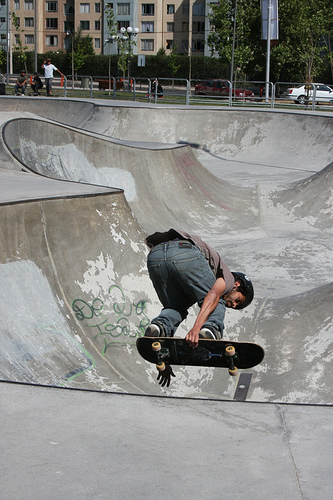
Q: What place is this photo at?
A: It is at the skate park.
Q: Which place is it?
A: It is a skate park.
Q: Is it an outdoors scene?
A: Yes, it is outdoors.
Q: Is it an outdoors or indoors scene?
A: It is outdoors.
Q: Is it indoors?
A: No, it is outdoors.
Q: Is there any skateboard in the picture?
A: Yes, there is a skateboard.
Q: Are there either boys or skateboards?
A: Yes, there is a skateboard.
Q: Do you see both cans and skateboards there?
A: No, there is a skateboard but no cans.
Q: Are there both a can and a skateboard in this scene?
A: No, there is a skateboard but no cans.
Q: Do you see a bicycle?
A: No, there are no bicycles.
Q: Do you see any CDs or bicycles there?
A: No, there are no bicycles or cds.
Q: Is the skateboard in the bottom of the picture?
A: Yes, the skateboard is in the bottom of the image.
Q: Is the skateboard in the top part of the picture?
A: No, the skateboard is in the bottom of the image.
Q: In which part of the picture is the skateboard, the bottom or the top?
A: The skateboard is in the bottom of the image.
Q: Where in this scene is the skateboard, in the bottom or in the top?
A: The skateboard is in the bottom of the image.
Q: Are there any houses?
A: No, there are no houses.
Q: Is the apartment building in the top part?
A: Yes, the apartment building is in the top of the image.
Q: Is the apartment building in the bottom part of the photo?
A: No, the apartment building is in the top of the image.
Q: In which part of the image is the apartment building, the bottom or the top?
A: The apartment building is in the top of the image.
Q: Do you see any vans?
A: No, there are no vans.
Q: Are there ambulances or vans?
A: No, there are no vans or ambulances.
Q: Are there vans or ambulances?
A: No, there are no vans or ambulances.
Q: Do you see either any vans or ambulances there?
A: No, there are no vans or ambulances.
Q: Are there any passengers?
A: No, there are no passengers.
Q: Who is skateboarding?
A: The man is skateboarding.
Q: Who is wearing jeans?
A: The man is wearing jeans.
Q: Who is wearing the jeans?
A: The man is wearing jeans.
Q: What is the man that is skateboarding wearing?
A: The man is wearing jeans.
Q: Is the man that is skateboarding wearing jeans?
A: Yes, the man is wearing jeans.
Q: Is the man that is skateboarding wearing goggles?
A: No, the man is wearing jeans.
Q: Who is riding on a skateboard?
A: The man is riding on a skateboard.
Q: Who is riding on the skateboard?
A: The man is riding on a skateboard.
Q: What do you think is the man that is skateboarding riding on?
A: The man is riding on a skateboard.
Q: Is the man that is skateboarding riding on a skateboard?
A: Yes, the man is riding on a skateboard.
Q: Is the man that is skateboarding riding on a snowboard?
A: No, the man is riding on a skateboard.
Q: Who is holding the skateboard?
A: The man is holding the skateboard.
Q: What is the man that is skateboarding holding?
A: The man is holding the skateboard.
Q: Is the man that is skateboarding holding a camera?
A: No, the man is holding the skateboard.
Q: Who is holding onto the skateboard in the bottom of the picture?
A: The man is holding onto the skateboard.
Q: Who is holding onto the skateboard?
A: The man is holding onto the skateboard.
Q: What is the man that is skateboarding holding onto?
A: The man is holding onto the skateboard.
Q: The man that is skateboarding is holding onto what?
A: The man is holding onto the skateboard.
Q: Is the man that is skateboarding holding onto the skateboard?
A: Yes, the man is holding onto the skateboard.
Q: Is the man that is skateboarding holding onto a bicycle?
A: No, the man is holding onto the skateboard.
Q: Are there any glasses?
A: No, there are no glasses.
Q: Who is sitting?
A: The man is sitting.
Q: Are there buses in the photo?
A: No, there are no buses.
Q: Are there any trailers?
A: No, there are no trailers.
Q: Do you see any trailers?
A: No, there are no trailers.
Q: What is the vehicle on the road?
A: The vehicle is a car.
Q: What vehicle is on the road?
A: The vehicle is a car.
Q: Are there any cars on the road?
A: Yes, there is a car on the road.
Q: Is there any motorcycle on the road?
A: No, there is a car on the road.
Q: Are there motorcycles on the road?
A: No, there is a car on the road.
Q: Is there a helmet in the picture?
A: Yes, there is a helmet.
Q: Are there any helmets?
A: Yes, there is a helmet.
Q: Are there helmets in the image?
A: Yes, there is a helmet.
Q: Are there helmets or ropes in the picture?
A: Yes, there is a helmet.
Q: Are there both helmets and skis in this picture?
A: No, there is a helmet but no skis.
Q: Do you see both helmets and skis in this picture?
A: No, there is a helmet but no skis.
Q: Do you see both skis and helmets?
A: No, there is a helmet but no skis.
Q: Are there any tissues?
A: No, there are no tissues.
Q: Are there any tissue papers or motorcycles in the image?
A: No, there are no tissue papers or motorcycles.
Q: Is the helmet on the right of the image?
A: Yes, the helmet is on the right of the image.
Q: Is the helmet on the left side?
A: No, the helmet is on the right of the image.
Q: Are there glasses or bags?
A: No, there are no glasses or bags.